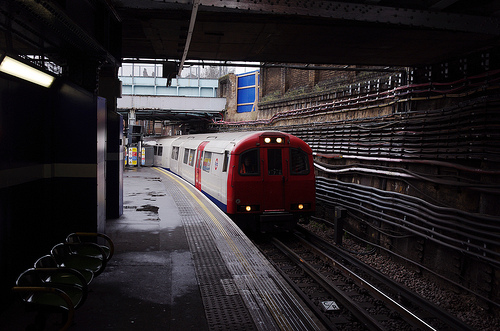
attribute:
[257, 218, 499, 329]
tracks — rusted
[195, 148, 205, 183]
doors — closed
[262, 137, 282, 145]
lights —  two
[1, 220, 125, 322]
seating area — dark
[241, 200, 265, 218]
headlight — head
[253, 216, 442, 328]
train tracks — section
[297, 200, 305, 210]
headlight — small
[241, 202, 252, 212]
headlight — small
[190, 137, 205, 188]
doors — red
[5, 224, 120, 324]
chairs — metal , row 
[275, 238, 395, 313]
some tracks — some 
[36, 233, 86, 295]
seats — black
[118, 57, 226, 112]
bridge — blue, grey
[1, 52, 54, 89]
tube light — tube 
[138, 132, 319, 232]
train — red, grey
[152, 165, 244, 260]
line — yellow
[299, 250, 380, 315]
tracks — metal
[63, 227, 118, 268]
seat —  some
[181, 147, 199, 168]
windows — side 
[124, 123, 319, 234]
train — side 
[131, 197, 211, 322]
platform — stone , metal 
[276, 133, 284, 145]
light — on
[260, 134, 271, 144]
light — on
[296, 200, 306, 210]
light — on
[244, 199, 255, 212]
light — on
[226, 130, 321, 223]
front — red